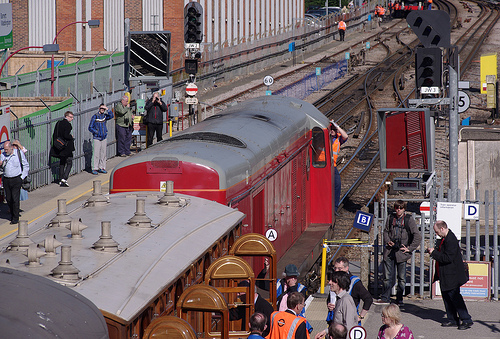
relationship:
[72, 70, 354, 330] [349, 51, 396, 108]
train on track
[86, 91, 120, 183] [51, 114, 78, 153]
man in suit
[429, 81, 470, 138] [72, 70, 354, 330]
signal for train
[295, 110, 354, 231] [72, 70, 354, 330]
door of train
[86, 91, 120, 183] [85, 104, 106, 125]
man has shoulder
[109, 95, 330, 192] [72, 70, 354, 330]
roof of train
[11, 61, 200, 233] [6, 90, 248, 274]
people at platform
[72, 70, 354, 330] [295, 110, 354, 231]
train has door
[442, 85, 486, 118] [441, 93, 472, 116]
sign has letter